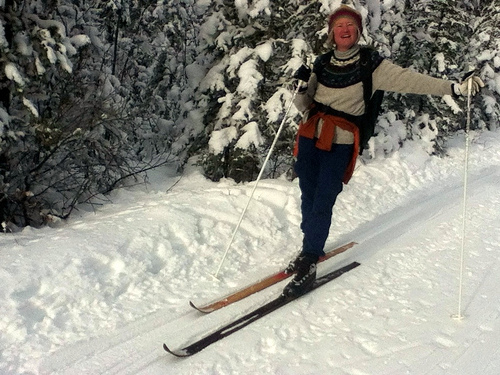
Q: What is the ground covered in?
A: Snow.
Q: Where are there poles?
A: Woman's hands.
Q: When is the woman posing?
A: Cold sunny day.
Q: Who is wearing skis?
A: Woman posing.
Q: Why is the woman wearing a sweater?
A: Cold weather.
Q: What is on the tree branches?
A: Snow.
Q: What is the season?
A: Winter.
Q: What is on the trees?
A: Snow.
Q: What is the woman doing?
A: Skiing.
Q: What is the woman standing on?
A: Skis.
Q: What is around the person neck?
A: Scarf.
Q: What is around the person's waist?
A: Sweater.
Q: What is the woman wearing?
A: Sweater.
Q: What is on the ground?
A: Snow.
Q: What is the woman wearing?
A: Dark pants.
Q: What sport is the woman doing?
A: Skiing.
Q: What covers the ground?
A: Snow.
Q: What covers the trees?
A: Snow.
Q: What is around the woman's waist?
A: Sweater.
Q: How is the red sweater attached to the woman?
A: Tied around her waist.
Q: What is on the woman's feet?
A: Skis.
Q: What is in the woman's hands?
A: Ski poles.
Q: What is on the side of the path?
A: Trees.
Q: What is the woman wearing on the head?
A: A hat.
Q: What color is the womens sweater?
A: Grey.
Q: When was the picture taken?
A: During the day.